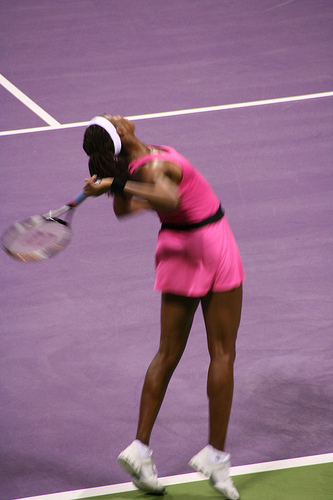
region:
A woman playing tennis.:
[21, 110, 250, 499]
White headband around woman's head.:
[80, 110, 133, 159]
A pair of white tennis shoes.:
[115, 439, 242, 498]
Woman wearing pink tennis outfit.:
[73, 112, 247, 294]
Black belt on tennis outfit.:
[152, 209, 231, 231]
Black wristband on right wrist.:
[108, 173, 127, 193]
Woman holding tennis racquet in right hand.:
[0, 112, 242, 260]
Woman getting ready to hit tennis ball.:
[2, 109, 252, 492]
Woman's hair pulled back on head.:
[79, 108, 139, 197]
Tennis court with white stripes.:
[3, 11, 323, 497]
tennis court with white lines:
[1, 1, 332, 497]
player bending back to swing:
[3, 113, 247, 498]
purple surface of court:
[2, 1, 328, 498]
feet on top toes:
[119, 440, 239, 498]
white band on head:
[89, 116, 121, 155]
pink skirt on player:
[125, 146, 241, 295]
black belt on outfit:
[162, 203, 225, 233]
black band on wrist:
[86, 175, 126, 194]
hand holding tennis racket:
[3, 175, 101, 261]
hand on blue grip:
[74, 176, 101, 205]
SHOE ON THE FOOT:
[112, 441, 172, 494]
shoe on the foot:
[189, 446, 254, 496]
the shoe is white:
[201, 459, 232, 484]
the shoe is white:
[126, 441, 163, 490]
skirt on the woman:
[141, 220, 240, 288]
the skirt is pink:
[192, 244, 234, 264]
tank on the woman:
[195, 178, 219, 206]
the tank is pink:
[193, 176, 215, 206]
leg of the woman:
[210, 329, 229, 451]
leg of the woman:
[120, 314, 178, 446]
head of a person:
[72, 104, 164, 181]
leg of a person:
[130, 299, 225, 431]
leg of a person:
[200, 337, 260, 437]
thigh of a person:
[153, 299, 199, 333]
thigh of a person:
[193, 292, 260, 357]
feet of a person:
[92, 440, 174, 498]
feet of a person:
[199, 449, 261, 494]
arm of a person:
[126, 171, 159, 210]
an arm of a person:
[129, 171, 181, 198]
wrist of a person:
[110, 165, 139, 199]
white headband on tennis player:
[91, 117, 124, 156]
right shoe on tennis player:
[188, 443, 241, 498]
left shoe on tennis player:
[107, 437, 171, 495]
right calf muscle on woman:
[206, 361, 225, 397]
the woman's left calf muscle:
[140, 361, 170, 397]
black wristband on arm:
[107, 174, 128, 192]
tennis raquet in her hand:
[0, 180, 95, 273]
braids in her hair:
[81, 125, 124, 176]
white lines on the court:
[0, 450, 330, 499]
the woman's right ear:
[114, 126, 129, 138]